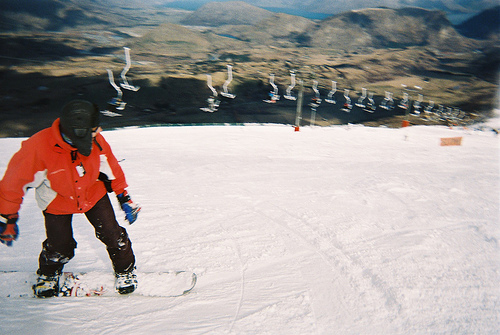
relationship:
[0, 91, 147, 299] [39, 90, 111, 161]
person with hat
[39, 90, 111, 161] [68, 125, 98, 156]
hat has flaps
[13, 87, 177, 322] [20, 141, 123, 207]
person wearing jacket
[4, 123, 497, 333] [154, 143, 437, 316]
snow on ground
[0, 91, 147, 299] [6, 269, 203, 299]
person on snowboard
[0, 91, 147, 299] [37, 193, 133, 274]
person has pants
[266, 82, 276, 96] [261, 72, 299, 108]
person on ski lift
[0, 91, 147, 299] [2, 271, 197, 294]
person on snowboard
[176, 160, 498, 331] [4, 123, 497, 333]
marks in snow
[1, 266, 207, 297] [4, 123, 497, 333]
showboard being used in snow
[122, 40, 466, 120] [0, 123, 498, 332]
lift on top of slope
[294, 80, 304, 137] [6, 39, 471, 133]
pole holds lift line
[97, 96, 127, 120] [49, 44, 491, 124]
chair on ski lift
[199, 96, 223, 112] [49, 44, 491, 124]
chair on ski lift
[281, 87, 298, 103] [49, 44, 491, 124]
chair on ski lift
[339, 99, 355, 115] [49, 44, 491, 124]
chair on ski lift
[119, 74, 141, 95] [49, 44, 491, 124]
chair on ski lift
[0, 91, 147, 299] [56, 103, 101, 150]
person wearing hat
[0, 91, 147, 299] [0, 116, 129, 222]
person wearing coat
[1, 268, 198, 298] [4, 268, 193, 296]
showboard with snow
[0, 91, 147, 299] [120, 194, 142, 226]
person wearing glove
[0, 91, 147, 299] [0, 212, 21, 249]
person wearing glove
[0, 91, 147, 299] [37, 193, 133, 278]
person wearing pants